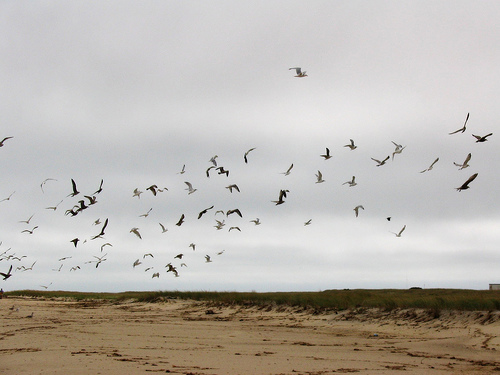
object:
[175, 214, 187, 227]
birds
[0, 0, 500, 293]
sky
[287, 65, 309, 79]
bird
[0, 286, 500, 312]
grass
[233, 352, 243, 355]
footprints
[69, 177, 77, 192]
wing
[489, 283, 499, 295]
building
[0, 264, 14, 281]
2 lifted wings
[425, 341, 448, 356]
part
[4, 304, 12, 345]
edge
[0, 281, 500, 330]
hill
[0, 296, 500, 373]
sand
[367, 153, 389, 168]
bird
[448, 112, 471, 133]
outstretched wings